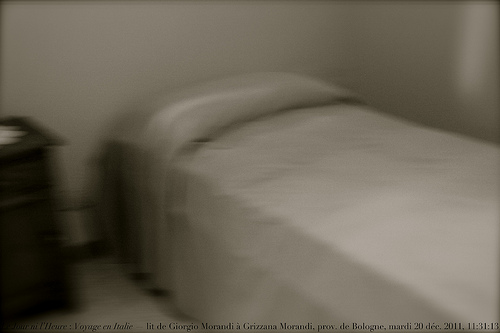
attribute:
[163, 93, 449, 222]
bed — white, made, small, blurry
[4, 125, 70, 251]
dresser — brown, small, blurry, wooden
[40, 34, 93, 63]
wall — white, blurry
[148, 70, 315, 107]
pillows — white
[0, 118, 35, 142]
papers — white, blury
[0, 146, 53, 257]
table — brown, wooden, blurry, old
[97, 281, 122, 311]
ground — white, blurry